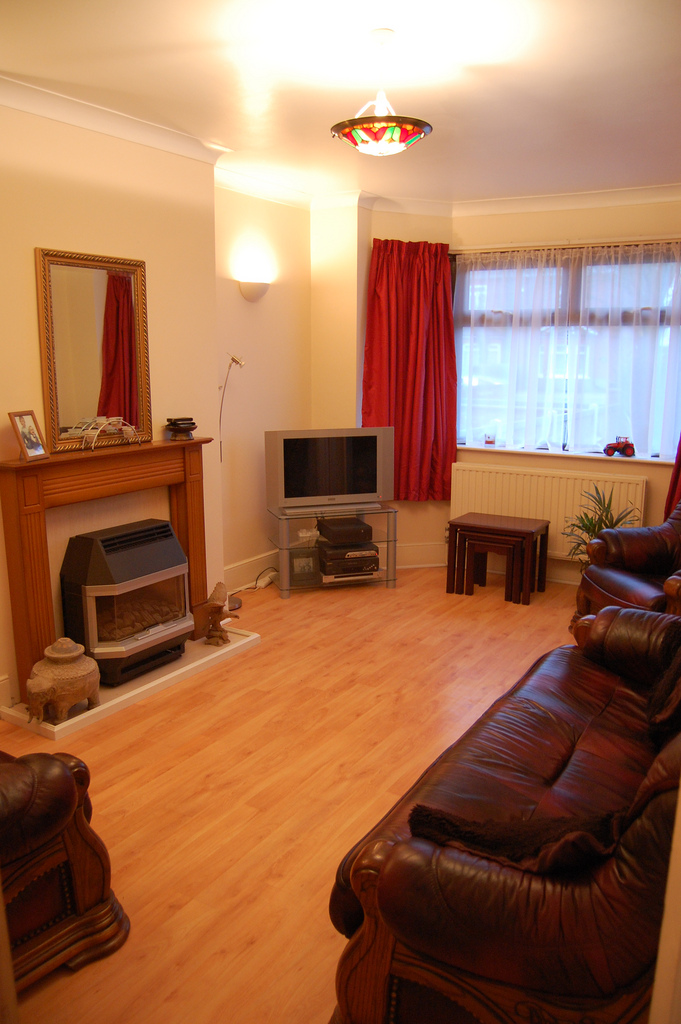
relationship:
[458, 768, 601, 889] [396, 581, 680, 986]
cushion on couch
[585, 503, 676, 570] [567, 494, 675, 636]
cushion on couch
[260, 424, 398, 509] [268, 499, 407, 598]
tv on stand